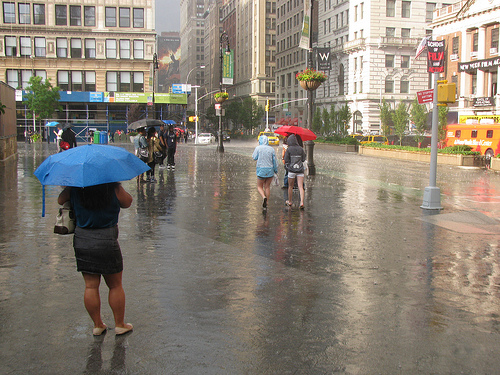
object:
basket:
[306, 80, 323, 90]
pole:
[304, 0, 316, 176]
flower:
[296, 73, 299, 77]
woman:
[55, 180, 132, 338]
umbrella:
[33, 143, 151, 191]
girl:
[283, 133, 307, 210]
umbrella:
[272, 124, 316, 142]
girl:
[251, 134, 278, 210]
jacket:
[251, 134, 278, 177]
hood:
[258, 135, 269, 145]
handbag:
[52, 203, 75, 236]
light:
[188, 116, 193, 123]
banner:
[297, 0, 314, 52]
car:
[194, 132, 216, 145]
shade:
[85, 71, 95, 85]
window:
[85, 69, 94, 92]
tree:
[379, 96, 391, 143]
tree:
[391, 99, 409, 146]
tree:
[409, 96, 428, 148]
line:
[375, 97, 429, 149]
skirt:
[71, 226, 125, 275]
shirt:
[63, 182, 121, 229]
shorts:
[287, 171, 305, 179]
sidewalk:
[0, 137, 499, 375]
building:
[0, 1, 159, 139]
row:
[2, 66, 145, 93]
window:
[132, 69, 143, 93]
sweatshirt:
[284, 133, 307, 175]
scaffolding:
[16, 101, 112, 145]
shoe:
[114, 322, 134, 335]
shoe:
[92, 323, 106, 335]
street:
[222, 136, 499, 216]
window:
[5, 67, 20, 90]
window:
[4, 35, 16, 56]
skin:
[86, 287, 100, 315]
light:
[435, 83, 458, 104]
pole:
[422, 72, 442, 208]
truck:
[444, 120, 500, 158]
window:
[131, 39, 144, 61]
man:
[133, 127, 149, 182]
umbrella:
[127, 118, 166, 131]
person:
[167, 125, 177, 170]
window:
[384, 78, 393, 93]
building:
[273, 0, 431, 141]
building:
[233, 2, 275, 135]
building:
[429, 1, 497, 137]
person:
[53, 124, 64, 153]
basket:
[216, 92, 229, 102]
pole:
[216, 30, 225, 152]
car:
[257, 131, 280, 146]